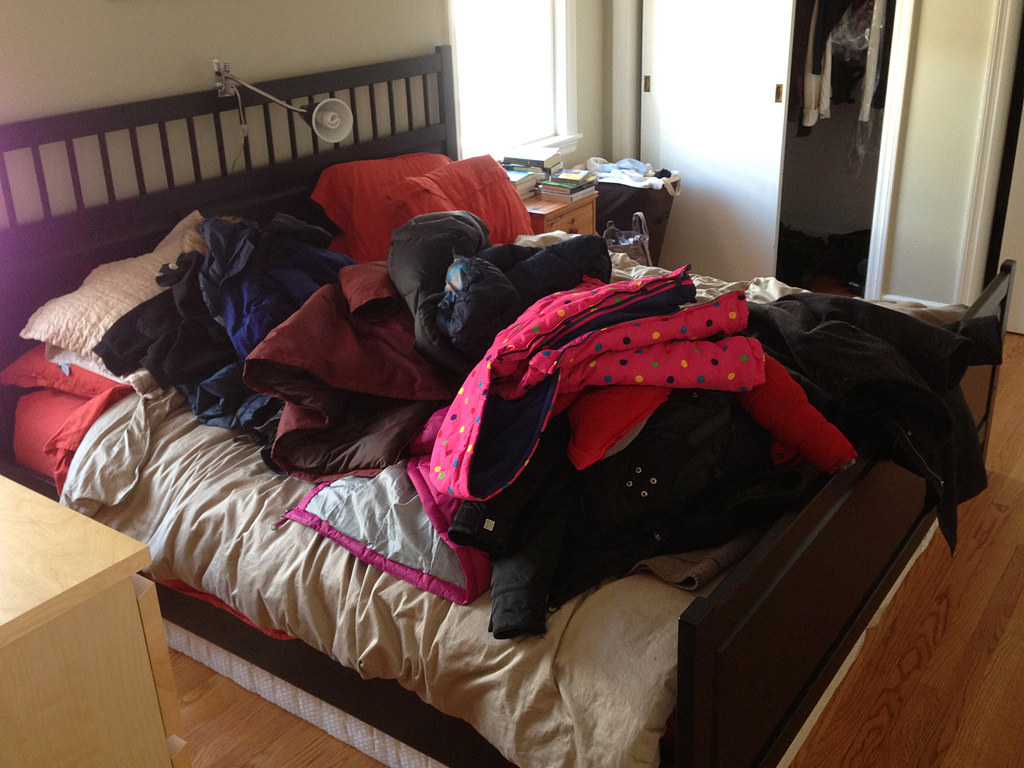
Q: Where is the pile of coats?
A: On the bed.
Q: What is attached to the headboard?
A: Lamp.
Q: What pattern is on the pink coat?
A: Polka dots.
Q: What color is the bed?
A: Brown.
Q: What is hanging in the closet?
A: Clothes.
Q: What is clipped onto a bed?
A: A light.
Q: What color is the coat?
A: Pink.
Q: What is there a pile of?
A: Coats.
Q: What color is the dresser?
A: Brown.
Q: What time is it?
A: Afternoon.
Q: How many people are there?
A: None.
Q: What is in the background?
A: A closet.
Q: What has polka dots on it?
A: The jacket.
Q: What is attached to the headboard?
A: A light.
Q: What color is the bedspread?
A: Tan.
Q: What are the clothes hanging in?
A: Closet.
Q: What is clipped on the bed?
A: Lamp.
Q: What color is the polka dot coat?
A: Pink.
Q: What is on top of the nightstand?
A: Books.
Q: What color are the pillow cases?
A: Red.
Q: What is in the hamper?
A: Clothes.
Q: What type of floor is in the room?
A: Wood.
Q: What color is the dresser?
A: Tan.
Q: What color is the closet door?
A: White.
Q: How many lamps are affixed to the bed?
A: 1.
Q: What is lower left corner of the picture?
A: A dresser.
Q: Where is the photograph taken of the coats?
A: Bedroom.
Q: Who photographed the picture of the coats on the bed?
A: The homeowner.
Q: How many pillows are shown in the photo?
A: 4.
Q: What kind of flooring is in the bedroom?
A: Wooden.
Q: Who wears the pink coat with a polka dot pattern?
A: A girl.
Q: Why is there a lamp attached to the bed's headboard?
A: For reading at night.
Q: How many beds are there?
A: 1.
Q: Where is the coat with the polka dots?
A: On top of the pile.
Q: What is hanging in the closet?
A: Clothes.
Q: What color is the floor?
A: Brown.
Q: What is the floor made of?
A: Wood.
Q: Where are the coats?
A: Piled on the bed.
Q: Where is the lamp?
A: On the headboard.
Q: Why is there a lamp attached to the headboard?
A: For reading.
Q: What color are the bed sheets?
A: Orange.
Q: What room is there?
A: Bedroom.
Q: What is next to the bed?
A: Night stand.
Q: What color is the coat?
A: Pink.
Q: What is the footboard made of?
A: Wood.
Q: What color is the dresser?
A: Tan.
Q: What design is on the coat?
A: Dots.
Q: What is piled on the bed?
A: Clothes.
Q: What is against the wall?
A: Headboard.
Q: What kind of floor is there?
A: Hard wood.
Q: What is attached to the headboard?
A: Lamp.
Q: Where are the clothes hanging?
A: In a closet.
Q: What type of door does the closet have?
A: A sliding door.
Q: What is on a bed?
A: Many jackets.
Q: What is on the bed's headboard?
A: A lamp.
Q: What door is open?
A: The closet door.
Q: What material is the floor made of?
A: Wood.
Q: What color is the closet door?
A: White.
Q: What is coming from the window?
A: Bright light.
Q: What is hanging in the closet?
A: Clothes are in the closet.